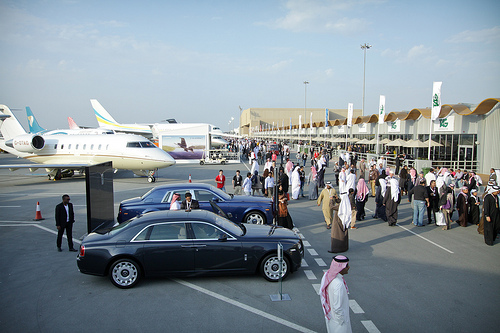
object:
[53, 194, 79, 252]
person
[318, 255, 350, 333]
person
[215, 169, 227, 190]
person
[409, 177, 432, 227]
person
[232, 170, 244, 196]
person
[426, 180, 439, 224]
person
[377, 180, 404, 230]
person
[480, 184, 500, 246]
person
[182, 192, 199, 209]
person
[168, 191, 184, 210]
person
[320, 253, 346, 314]
head covering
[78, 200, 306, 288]
car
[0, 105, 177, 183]
plane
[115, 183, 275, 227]
car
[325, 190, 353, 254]
people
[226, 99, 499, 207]
building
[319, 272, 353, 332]
clothes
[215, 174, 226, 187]
shirt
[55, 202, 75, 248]
suit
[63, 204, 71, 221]
shirt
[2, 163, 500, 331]
ground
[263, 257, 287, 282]
rims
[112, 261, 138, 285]
rims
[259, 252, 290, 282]
tire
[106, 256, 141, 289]
tire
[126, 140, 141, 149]
window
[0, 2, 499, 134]
sky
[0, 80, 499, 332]
airport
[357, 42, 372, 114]
light pole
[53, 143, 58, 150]
window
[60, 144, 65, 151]
window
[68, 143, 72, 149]
window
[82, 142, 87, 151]
window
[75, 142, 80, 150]
window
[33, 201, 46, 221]
traffic cone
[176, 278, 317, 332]
line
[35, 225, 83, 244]
line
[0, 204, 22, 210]
line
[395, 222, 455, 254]
line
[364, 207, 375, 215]
line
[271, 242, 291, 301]
sign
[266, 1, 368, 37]
cloud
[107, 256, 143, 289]
back right wheel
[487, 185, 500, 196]
scarf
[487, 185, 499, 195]
head